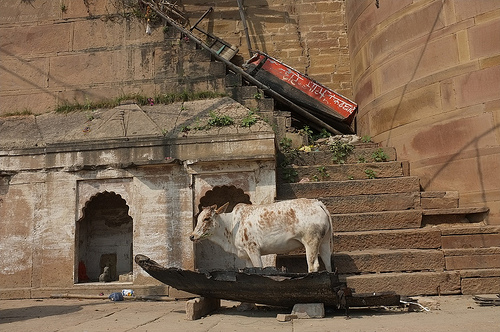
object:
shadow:
[0, 301, 116, 323]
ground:
[0, 297, 498, 329]